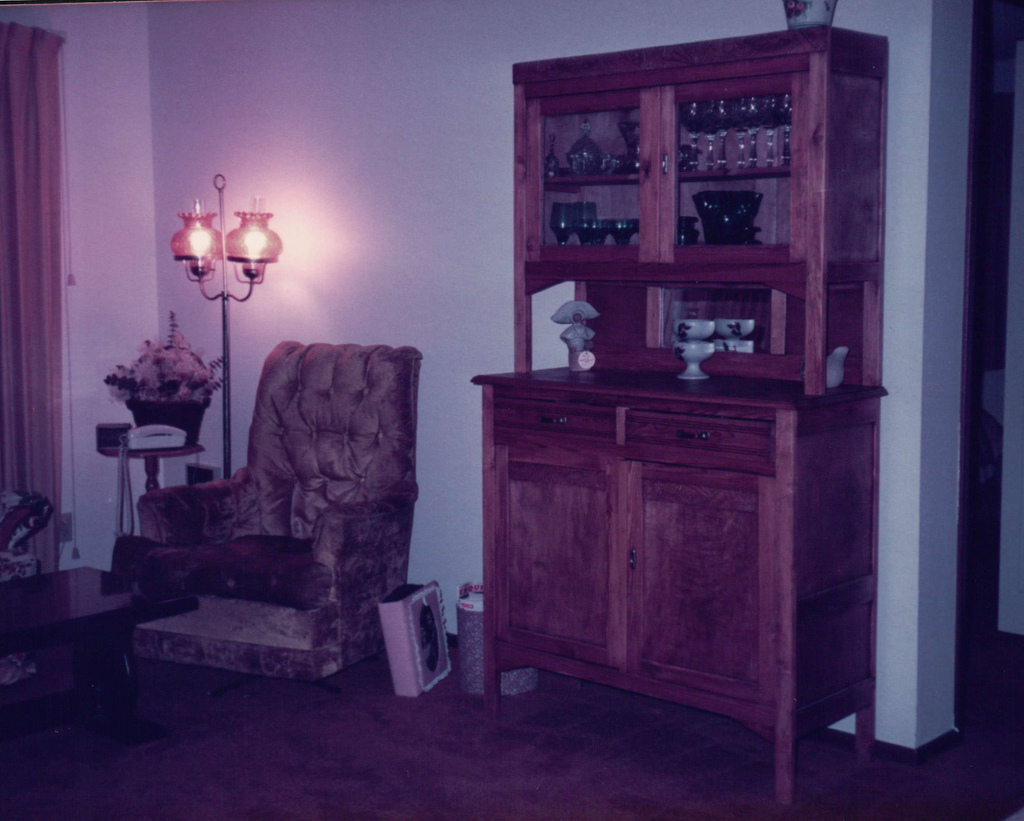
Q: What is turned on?
A: The lights.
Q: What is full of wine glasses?
A: The top corner shelf.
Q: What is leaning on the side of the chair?
A: A light colored book.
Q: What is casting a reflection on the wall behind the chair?
A: The lamp.